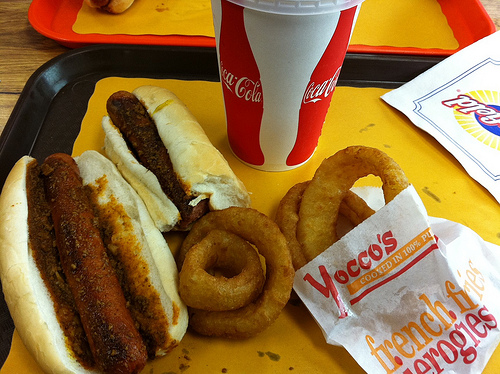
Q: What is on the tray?
A: Food and beverage.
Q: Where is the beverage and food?
A: On a tray.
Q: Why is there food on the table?
A: To eat.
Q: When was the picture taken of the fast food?
A: Daytime.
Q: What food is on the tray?
A: Onion rings and chili dogs.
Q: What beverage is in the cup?
A: Coca-Cola.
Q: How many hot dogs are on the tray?
A: One and a half.